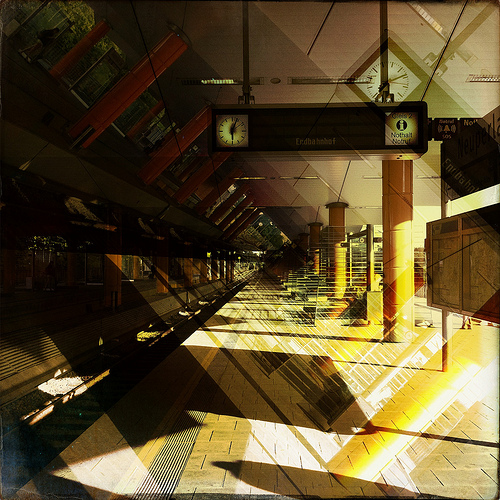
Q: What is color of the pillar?
A: Yellow.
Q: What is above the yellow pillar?
A: The the reflection of the clock.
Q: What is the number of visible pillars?
A: Three.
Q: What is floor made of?
A: Tiles.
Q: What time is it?
A: 6:05.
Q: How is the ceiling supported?
A: By yellow poles.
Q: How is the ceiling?
A: Reflective.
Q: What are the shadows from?
A: Sun.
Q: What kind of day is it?
A: Sunny.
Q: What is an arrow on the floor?
A: Shadow.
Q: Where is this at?
A: Terminal.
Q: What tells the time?
A: Clock.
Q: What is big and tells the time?
A: Clock.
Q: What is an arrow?
A: Shadow.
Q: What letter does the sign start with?
A: E.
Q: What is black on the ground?
A: Shadow.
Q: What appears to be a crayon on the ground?
A: Shadow.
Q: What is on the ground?
A: Steel grates.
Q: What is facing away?
A: Large wooden sign.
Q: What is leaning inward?
A: Red pillars.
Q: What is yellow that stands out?
A: The pillars.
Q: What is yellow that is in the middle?
A: The pillars.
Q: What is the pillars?
A: Yellow.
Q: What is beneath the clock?
A: Yellow pillars.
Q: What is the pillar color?
A: Yellow.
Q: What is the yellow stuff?
A: The pillars.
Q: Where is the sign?
A: Train station.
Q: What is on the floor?
A: Tile.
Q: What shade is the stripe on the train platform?
A: Yellow.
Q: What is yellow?
A: The posts.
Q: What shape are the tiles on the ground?
A: Rectangle.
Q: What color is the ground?
A: Tan.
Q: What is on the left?
A: Train tracks.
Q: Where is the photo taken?
A: In the subway.